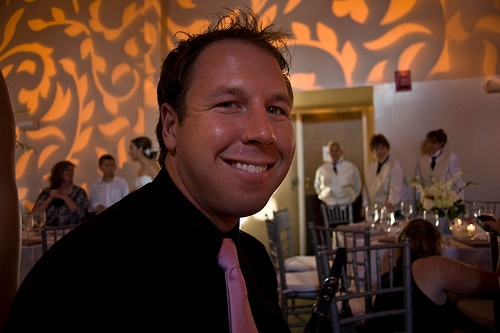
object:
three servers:
[313, 129, 466, 208]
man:
[0, 6, 296, 331]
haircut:
[156, 7, 292, 169]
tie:
[216, 237, 260, 332]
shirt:
[7, 168, 291, 332]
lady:
[128, 138, 162, 190]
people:
[82, 154, 129, 205]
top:
[134, 174, 154, 189]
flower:
[433, 185, 451, 199]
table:
[328, 219, 499, 286]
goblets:
[364, 204, 380, 229]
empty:
[265, 202, 414, 332]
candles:
[465, 222, 476, 234]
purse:
[306, 247, 353, 332]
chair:
[315, 244, 415, 331]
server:
[413, 129, 461, 193]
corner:
[462, 139, 499, 189]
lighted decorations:
[0, 0, 499, 224]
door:
[299, 106, 366, 250]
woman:
[368, 219, 499, 331]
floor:
[280, 298, 498, 332]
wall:
[375, 78, 499, 206]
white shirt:
[88, 175, 127, 208]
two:
[453, 215, 478, 237]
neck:
[159, 154, 240, 236]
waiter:
[314, 139, 362, 210]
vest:
[319, 164, 354, 211]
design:
[13, 41, 59, 114]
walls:
[2, 3, 149, 158]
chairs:
[265, 211, 327, 331]